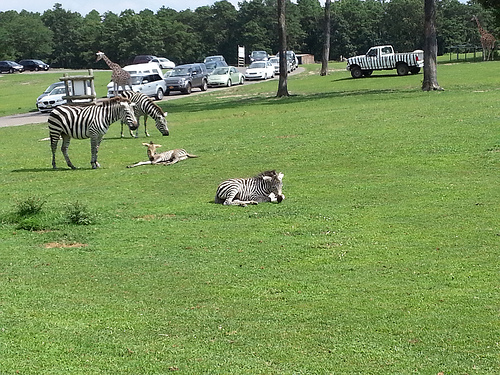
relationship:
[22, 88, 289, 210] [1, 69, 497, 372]
zebras are in field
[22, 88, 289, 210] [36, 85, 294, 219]
zebras have old and young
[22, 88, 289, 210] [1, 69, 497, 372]
zebras are laying on field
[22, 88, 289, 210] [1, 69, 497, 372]
zebras are laying in field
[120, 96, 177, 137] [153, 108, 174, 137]
zebra has head down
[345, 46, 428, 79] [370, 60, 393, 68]
truck has zebra paint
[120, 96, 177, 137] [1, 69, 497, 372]
zebra lounges in field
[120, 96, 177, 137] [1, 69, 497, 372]
zebra stands in field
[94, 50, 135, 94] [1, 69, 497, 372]
giraffe in field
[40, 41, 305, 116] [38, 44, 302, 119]
tourists are in cars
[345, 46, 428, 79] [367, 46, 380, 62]
truck for staff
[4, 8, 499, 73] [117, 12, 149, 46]
trees have leaves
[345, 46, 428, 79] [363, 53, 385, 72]
truck has stripes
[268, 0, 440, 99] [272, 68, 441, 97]
three trees have trunks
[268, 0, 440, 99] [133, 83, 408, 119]
three trees have shadows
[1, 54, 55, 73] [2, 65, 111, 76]
two cars are in parking lot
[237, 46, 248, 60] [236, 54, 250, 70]
sign on post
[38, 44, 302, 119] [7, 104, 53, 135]
cars are on road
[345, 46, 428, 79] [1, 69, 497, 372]
truck in field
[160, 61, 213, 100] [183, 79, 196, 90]
car has wheel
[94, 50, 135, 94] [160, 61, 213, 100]
giraffe near car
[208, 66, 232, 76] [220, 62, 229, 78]
front glass has wiper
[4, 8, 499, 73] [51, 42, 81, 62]
trees have branches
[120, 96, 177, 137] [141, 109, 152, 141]
zebra has leg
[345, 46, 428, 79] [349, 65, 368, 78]
truck has wheel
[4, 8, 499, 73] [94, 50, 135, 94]
trees are with giraffe